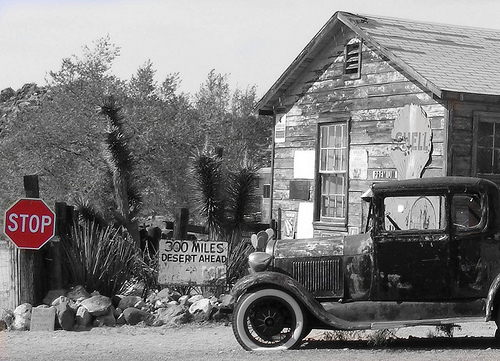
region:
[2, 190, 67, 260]
large red oblong sign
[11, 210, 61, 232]
white words on red sign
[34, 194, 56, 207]
white border on red sign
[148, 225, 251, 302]
small white sign in the garden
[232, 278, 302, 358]
deflated wheel on car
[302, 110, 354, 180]
window bars in the side of the house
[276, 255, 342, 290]
small grate at side of car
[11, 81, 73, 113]
rocks on the hill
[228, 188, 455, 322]
abandoned car in front of house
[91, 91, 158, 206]
pine needles on tall tree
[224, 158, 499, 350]
vehicle on the street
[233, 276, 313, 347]
front tire on vehicle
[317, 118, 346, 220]
window on the building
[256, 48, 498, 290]
building behind the vehicle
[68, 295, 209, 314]
rocks on the ground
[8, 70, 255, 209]
trees in the distance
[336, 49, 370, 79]
vent on side of building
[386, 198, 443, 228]
window area of vehicle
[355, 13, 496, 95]
roof of the building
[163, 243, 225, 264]
lettering and information and numbers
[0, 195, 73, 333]
A red stop sign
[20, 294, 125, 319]
A heap of grey stones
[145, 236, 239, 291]
A white deriction banner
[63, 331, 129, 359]
A rough mourum road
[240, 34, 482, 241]
A old timber house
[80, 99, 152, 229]
A tall cactus tree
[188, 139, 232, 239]
A tall cactus tree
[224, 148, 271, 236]
A tall cactus tree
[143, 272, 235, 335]
A head of grey stones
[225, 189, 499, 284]
A black old car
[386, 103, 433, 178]
Old Shell gas station sign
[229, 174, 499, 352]
Old and warn antique car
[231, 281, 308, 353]
Flat tire with white wall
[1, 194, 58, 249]
Posted red stop sign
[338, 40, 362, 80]
Attic vent in old building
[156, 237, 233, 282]
Desert sign in brush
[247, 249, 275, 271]
Front driver side headlight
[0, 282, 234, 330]
Rocks line the road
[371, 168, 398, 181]
Premium sign on building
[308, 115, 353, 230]
Tall and narrow window